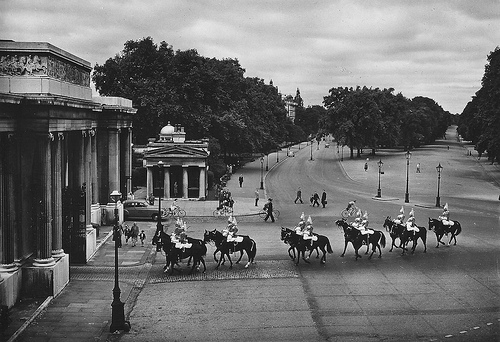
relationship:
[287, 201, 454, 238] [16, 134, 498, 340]
people on street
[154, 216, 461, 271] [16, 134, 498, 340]
horses on street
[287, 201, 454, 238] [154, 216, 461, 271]
people on horses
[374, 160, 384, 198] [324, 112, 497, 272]
light on street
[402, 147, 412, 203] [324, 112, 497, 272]
light on street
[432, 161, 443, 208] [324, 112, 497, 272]
light on street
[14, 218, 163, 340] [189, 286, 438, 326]
sidewalk near street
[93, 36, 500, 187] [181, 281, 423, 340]
tree in middle of street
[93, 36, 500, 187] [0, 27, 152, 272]
tree near building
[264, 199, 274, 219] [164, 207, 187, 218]
person on a bicycle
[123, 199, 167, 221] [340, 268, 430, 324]
car on road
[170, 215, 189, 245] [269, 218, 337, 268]
man on horses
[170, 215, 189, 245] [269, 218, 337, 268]
man riding horses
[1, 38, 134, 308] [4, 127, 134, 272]
building with columns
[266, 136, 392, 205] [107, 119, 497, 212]
road coming down hill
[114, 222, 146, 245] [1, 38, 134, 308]
family walking by building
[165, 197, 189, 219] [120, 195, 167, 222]
bicycle in front of car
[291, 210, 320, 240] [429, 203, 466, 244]
men on horses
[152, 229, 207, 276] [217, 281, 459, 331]
horses crossing street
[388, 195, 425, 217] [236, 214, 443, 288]
hats on horses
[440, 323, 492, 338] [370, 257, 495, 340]
dashes on street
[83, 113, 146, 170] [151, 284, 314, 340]
light on pavement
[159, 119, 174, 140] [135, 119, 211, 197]
dome on top of building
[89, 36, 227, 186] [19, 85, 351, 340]
tree bordering sidewalk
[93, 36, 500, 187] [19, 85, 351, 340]
tree bordering sidewalk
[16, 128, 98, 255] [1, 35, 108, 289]
pillars on front of building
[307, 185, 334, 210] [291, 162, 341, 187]
people crossing street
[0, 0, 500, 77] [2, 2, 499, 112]
cloud in sky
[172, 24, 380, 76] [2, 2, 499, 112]
cloud in sky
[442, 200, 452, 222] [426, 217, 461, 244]
man on horse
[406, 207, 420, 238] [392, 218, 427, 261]
man on horse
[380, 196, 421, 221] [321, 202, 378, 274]
man on horse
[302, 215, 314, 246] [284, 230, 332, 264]
man on horse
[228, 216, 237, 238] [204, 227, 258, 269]
man on horse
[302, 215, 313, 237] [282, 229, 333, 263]
man on horse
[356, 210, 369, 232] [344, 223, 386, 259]
man on horse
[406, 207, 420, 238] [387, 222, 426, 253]
man on horse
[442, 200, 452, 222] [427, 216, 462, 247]
man on horse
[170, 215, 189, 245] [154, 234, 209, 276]
man on horse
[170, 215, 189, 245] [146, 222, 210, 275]
man on horse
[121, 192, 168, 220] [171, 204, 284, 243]
car at intersection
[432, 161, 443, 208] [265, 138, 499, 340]
light beside street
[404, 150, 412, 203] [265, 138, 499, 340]
light beside street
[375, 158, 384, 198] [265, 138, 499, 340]
light beside street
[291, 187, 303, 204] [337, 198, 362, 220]
person on bicycle